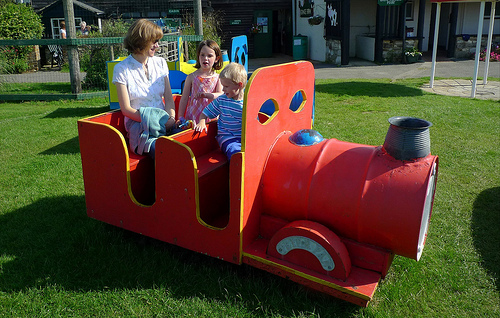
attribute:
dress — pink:
[190, 70, 220, 112]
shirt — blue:
[201, 100, 242, 139]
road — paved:
[13, 56, 465, 91]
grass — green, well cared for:
[7, 84, 413, 278]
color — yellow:
[288, 267, 340, 291]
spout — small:
[380, 112, 434, 159]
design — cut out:
[254, 87, 308, 131]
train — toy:
[65, 56, 441, 310]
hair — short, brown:
[122, 18, 163, 56]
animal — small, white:
[325, 6, 339, 27]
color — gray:
[354, 60, 420, 77]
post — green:
[8, 34, 61, 52]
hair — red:
[192, 39, 222, 68]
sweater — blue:
[134, 106, 169, 155]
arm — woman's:
[110, 69, 163, 125]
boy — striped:
[193, 60, 240, 150]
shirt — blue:
[203, 94, 241, 142]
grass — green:
[18, 95, 64, 202]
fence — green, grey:
[5, 33, 105, 90]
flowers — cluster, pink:
[470, 40, 497, 62]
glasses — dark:
[149, 32, 165, 43]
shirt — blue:
[205, 90, 246, 139]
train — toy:
[75, 71, 435, 296]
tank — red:
[266, 123, 437, 262]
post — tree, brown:
[61, 3, 91, 92]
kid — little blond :
[185, 33, 239, 162]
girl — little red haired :
[181, 35, 220, 119]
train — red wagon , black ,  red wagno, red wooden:
[65, 15, 455, 304]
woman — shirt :
[103, 13, 182, 154]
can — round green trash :
[281, 22, 323, 68]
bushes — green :
[3, 8, 40, 78]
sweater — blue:
[129, 100, 169, 145]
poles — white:
[430, 9, 445, 83]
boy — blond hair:
[198, 63, 265, 164]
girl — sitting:
[174, 32, 226, 135]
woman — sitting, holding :
[113, 15, 182, 172]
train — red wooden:
[68, 13, 431, 313]